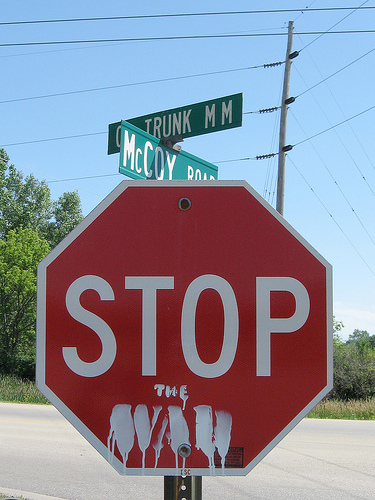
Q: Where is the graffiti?
A: On the sign.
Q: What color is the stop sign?
A: Red.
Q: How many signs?
A: Three.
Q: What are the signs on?
A: A pole.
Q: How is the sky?
A: Clear.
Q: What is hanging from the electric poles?
A: Wires.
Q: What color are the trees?
A: Green.